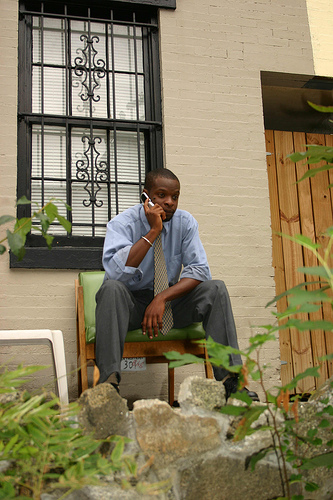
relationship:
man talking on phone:
[91, 170, 251, 400] [132, 184, 159, 220]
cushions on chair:
[136, 326, 143, 339] [74, 273, 204, 375]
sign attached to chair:
[123, 359, 144, 372] [70, 276, 219, 395]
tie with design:
[144, 230, 188, 331] [148, 238, 172, 292]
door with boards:
[248, 73, 329, 333] [270, 128, 320, 244]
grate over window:
[18, 0, 167, 243] [20, 12, 169, 235]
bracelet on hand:
[138, 232, 156, 246] [130, 193, 173, 247]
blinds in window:
[42, 43, 121, 112] [20, 12, 169, 235]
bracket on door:
[275, 380, 317, 406] [245, 111, 323, 427]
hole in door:
[313, 186, 330, 204] [249, 80, 325, 373]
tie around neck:
[151, 230, 174, 337] [131, 189, 177, 231]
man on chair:
[91, 166, 260, 409] [73, 256, 214, 370]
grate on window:
[28, 22, 167, 235] [16, 9, 163, 241]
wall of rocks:
[69, 330, 253, 483] [65, 370, 279, 480]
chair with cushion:
[81, 262, 206, 375] [95, 323, 187, 358]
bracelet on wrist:
[138, 232, 156, 246] [130, 218, 165, 244]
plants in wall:
[7, 371, 88, 484] [184, 101, 233, 197]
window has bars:
[21, 45, 93, 140] [64, 65, 130, 140]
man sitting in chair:
[91, 166, 260, 409] [76, 257, 207, 353]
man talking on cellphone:
[91, 166, 260, 409] [127, 182, 174, 228]